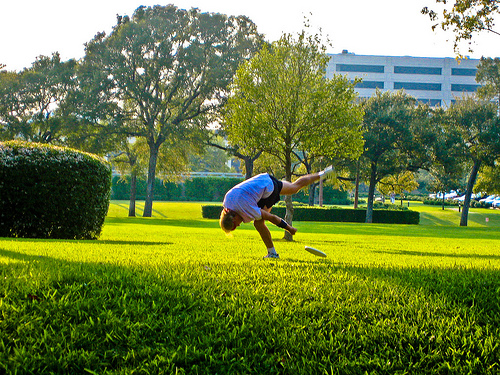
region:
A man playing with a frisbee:
[219, 153, 351, 282]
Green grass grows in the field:
[67, 270, 475, 367]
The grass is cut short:
[39, 268, 454, 371]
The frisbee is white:
[306, 246, 328, 266]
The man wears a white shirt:
[227, 175, 274, 220]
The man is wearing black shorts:
[262, 176, 285, 207]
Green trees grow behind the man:
[18, 26, 488, 221]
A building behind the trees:
[314, 43, 498, 200]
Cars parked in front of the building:
[429, 186, 496, 205]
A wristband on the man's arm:
[277, 218, 289, 235]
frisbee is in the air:
[285, 236, 368, 270]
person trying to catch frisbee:
[215, 191, 304, 261]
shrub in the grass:
[6, 123, 180, 266]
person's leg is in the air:
[230, 159, 399, 206]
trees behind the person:
[151, 37, 497, 195]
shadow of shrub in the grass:
[36, 198, 160, 281]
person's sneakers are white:
[311, 157, 351, 191]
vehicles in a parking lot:
[438, 153, 499, 210]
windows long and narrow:
[339, 51, 452, 104]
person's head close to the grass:
[172, 149, 261, 263]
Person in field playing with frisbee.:
[213, 156, 353, 271]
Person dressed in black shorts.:
[256, 164, 295, 211]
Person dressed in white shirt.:
[222, 169, 279, 225]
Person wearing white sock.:
[317, 163, 332, 183]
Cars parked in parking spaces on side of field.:
[435, 184, 499, 214]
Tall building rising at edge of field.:
[316, 41, 499, 201]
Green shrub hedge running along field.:
[311, 196, 427, 231]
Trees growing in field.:
[73, 2, 233, 233]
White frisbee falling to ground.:
[300, 240, 337, 270]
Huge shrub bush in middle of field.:
[6, 133, 113, 247]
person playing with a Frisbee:
[208, 158, 343, 264]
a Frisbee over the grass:
[296, 242, 341, 269]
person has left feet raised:
[207, 150, 347, 267]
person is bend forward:
[207, 145, 347, 270]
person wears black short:
[198, 140, 354, 271]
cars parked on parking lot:
[416, 182, 499, 213]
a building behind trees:
[303, 42, 499, 174]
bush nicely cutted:
[3, 133, 118, 249]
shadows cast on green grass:
[7, 233, 169, 284]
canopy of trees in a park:
[0, 0, 497, 169]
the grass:
[202, 280, 296, 365]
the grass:
[234, 333, 299, 365]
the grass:
[232, 301, 302, 357]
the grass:
[230, 282, 330, 362]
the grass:
[243, 317, 320, 372]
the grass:
[247, 348, 303, 373]